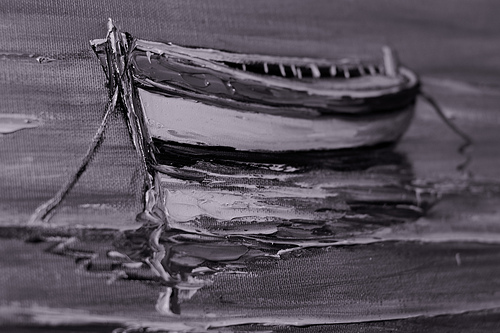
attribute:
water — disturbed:
[0, 1, 499, 331]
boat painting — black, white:
[1, 0, 495, 330]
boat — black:
[86, 21, 442, 173]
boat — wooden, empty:
[84, 15, 428, 180]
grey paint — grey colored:
[13, 44, 99, 121]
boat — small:
[86, 19, 494, 179]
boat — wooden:
[92, 15, 422, 160]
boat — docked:
[84, 16, 453, 200]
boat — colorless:
[65, 13, 468, 263]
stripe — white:
[139, 85, 416, 150]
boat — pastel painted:
[104, 32, 421, 159]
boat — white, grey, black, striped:
[101, 26, 489, 164]